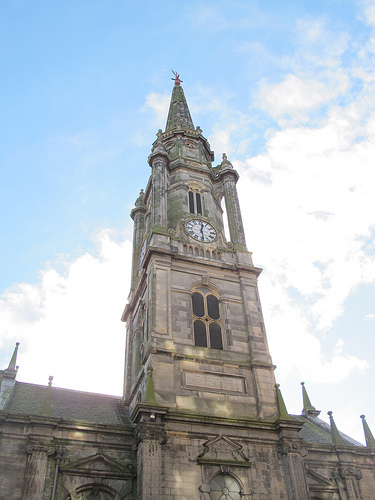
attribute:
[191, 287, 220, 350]
window — tower, black, gold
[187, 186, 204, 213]
window — tower, black, gold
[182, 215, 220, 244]
clock — white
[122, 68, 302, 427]
tower — triangular, pointy, large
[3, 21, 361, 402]
sky — blue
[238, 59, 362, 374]
clouds — white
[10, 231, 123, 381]
clouds — white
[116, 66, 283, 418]
tower — tall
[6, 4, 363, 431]
sky — blue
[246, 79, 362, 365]
clouds — white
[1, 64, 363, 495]
building — brown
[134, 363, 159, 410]
spire — dark green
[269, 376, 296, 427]
spire — dark green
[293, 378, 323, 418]
spire — dark green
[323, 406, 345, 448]
spire — dark green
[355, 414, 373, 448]
spire — dark green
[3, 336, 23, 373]
spire — dark green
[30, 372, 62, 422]
spire — dark green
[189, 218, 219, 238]
clock — white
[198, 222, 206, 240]
hands — black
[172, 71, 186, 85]
weathervane — red, metal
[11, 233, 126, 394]
clouds — white, bright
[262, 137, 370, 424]
clouds — bright, white